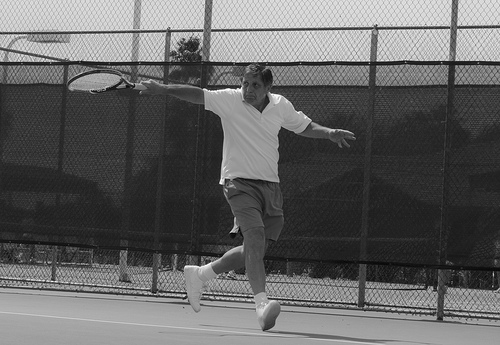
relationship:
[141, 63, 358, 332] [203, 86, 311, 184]
man in shirt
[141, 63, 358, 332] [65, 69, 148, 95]
man used tennis racquet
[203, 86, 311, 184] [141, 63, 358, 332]
shirt on man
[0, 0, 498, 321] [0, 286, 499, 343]
fence around tennis court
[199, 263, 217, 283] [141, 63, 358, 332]
sock on man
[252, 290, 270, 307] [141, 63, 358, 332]
sock on man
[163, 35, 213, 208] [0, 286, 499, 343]
tree outside tennis court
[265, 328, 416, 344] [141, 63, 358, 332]
shadow of man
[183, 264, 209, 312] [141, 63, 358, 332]
foot of man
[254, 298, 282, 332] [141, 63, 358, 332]
foot of man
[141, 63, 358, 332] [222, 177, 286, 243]
man wearing shorts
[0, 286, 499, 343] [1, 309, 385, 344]
tennis court has serving line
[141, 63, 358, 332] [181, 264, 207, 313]
man in shoe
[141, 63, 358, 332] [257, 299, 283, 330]
man in shoe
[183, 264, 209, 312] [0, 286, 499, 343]
foot off tennis court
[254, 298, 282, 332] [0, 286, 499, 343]
foot off tennis court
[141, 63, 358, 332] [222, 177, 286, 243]
man in shorts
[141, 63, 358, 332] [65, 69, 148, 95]
man holding tennis racquet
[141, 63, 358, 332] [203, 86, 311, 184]
man wearing shirt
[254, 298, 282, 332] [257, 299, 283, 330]
right foot with shoe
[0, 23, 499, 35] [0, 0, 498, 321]
top of fence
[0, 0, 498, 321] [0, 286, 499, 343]
fence at tennis court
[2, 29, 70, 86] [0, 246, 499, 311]
light in next court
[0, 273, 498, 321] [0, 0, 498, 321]
bottom of fence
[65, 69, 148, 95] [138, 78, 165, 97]
tennis racquet in hand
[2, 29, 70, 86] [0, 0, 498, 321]
light behind fence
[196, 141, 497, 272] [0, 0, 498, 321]
house behind fence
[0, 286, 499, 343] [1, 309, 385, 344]
tennis court with serving line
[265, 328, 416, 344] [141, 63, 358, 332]
shadow from man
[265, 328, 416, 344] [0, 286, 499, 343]
shadow on tennis court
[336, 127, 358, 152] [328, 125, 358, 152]
fingers on left hand